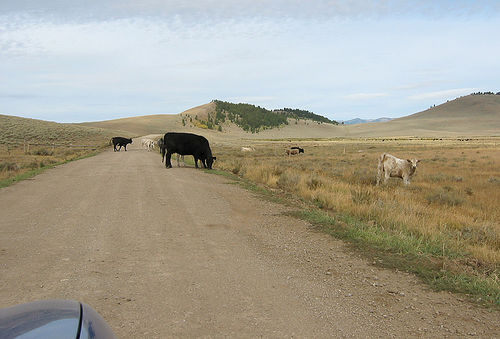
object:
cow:
[163, 132, 216, 169]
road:
[0, 133, 499, 338]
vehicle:
[0, 299, 121, 338]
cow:
[241, 147, 257, 152]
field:
[152, 135, 499, 309]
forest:
[180, 99, 344, 134]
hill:
[181, 99, 290, 133]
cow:
[111, 137, 133, 152]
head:
[205, 156, 216, 169]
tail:
[162, 136, 166, 164]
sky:
[0, 1, 500, 123]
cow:
[378, 153, 422, 185]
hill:
[432, 93, 500, 116]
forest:
[464, 89, 500, 98]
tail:
[380, 154, 386, 181]